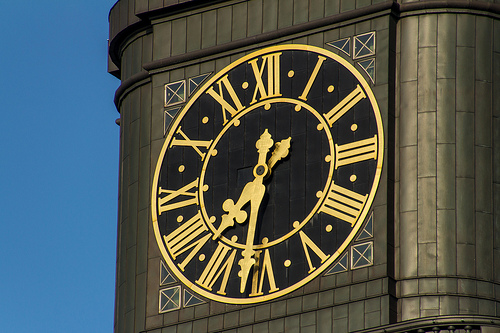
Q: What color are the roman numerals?
A: Gold.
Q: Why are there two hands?
A: For clock to tell time.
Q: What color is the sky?
A: Blue.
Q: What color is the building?
A: Grey.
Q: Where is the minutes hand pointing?
A: Down.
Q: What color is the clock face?
A: Black.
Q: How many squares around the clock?
A: Four.